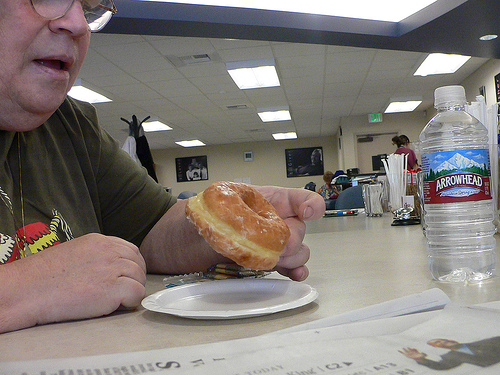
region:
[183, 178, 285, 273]
glazed donut above a white plate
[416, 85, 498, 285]
plastic water bottle is unopened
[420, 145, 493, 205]
label glued to water bottle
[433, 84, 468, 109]
white plastic lid on top of bottle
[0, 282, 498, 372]
newspaper on top of counter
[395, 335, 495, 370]
image of a person printed on the newspaper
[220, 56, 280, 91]
rectangular fluorescent light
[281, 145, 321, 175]
poster hanging on wall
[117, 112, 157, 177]
tall coat rack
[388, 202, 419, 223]
shiny silver bell on top of counter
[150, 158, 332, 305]
Man holding a doughnut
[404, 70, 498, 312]
Bottle of water on the table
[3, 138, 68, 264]
Man wearing a necklace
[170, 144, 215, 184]
Picture on the wall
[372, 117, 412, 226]
Straws in the cup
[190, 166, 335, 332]
The doughnut has glaze on it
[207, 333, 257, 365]
Newspaper on the table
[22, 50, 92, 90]
Man's mouth is open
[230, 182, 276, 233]
Hole in the doughnut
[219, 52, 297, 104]
Light on the ceiling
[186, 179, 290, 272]
A glazed doughnut being lifted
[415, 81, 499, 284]
A closed bottle of water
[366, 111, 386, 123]
Glowing letters above the designated exit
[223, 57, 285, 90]
Light fixture in the ceiling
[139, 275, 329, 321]
Small paper plate on a table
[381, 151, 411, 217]
A cup full of straws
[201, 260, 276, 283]
Two packets of crackers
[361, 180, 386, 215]
Napkins inside a napkin holder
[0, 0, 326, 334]
A person lifting a doughnut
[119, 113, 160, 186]
A rack with coats on it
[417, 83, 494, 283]
plastic water bottle on white table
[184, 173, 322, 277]
donut in mans hand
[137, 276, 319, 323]
white styrofoam plate under donut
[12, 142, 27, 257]
gold necklace around mans neck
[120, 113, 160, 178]
coat rack with many coats hanging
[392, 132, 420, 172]
woman in red standing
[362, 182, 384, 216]
silver napkin holder with napkins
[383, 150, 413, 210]
straw holder with many straws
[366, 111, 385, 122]
green and white exit sign over door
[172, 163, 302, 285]
A glazed donut for breakfast.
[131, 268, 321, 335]
White paper plate the donut was served on.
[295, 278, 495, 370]
Newspaper on the counter.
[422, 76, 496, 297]
Bottle of Arrowhead water.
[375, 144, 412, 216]
Straws in a jar for the taking.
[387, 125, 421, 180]
Woman preparing food on the grill.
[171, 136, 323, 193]
Pictures on the wall.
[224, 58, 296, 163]
Bright white overhead lights.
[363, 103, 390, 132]
Green exit sign over the door.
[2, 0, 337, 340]
A person holding a donut.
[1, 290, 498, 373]
An open newspaper.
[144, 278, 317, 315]
A small round paper plate.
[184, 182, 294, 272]
A golden brown glazed donut.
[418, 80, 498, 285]
A bottle of water.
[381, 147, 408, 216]
A bunch of straws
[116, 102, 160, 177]
A coat rack with coats on it.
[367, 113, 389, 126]
A green lit up EXIT sign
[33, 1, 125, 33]
A pair of eyeglasses.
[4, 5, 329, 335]
A person wearing glasses.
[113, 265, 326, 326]
a white paper plate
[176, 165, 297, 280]
a golden brown doughnut